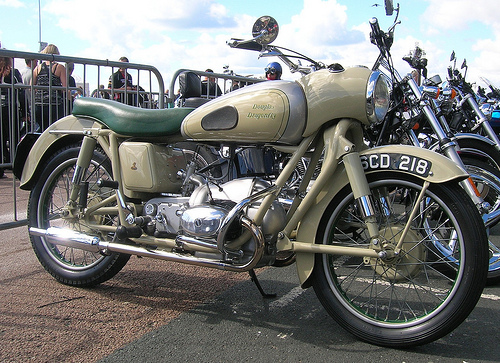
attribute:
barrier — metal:
[29, 50, 147, 112]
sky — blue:
[1, 2, 498, 95]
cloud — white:
[43, 1, 207, 42]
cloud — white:
[417, 1, 497, 34]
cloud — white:
[457, 35, 498, 92]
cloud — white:
[265, 1, 437, 88]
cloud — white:
[85, 30, 237, 82]